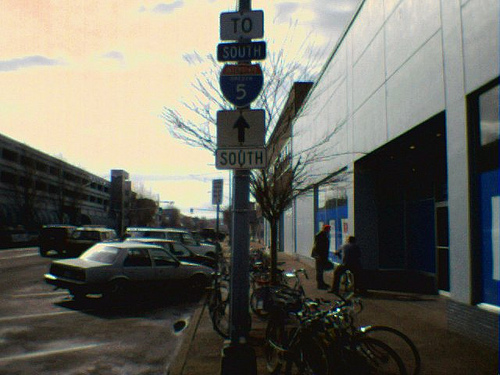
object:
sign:
[218, 9, 263, 40]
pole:
[230, 0, 255, 373]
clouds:
[95, 132, 117, 151]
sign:
[216, 40, 266, 61]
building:
[257, 0, 500, 313]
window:
[318, 171, 347, 209]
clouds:
[143, 68, 163, 81]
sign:
[215, 147, 267, 170]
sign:
[216, 108, 267, 150]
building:
[0, 135, 132, 250]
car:
[43, 242, 213, 304]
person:
[310, 224, 334, 291]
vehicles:
[65, 227, 120, 258]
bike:
[342, 266, 363, 294]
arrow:
[232, 112, 251, 143]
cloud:
[0, 0, 23, 23]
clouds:
[1, 56, 37, 77]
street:
[0, 199, 371, 375]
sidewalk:
[176, 247, 438, 375]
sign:
[219, 63, 265, 109]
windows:
[21, 154, 36, 168]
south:
[220, 150, 264, 166]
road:
[0, 225, 178, 375]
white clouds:
[196, 10, 218, 31]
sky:
[5, 1, 356, 221]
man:
[328, 235, 369, 296]